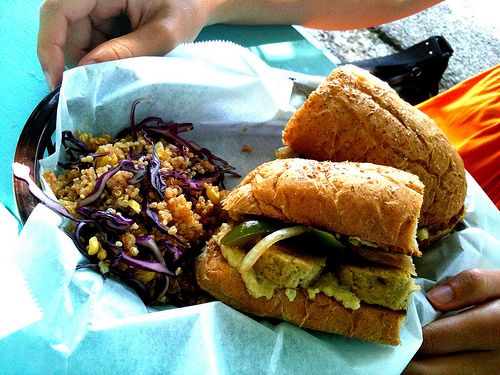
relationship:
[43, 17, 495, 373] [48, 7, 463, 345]
bench next to table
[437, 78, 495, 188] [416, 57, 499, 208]
wrinkles are on shirt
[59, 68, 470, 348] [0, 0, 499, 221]
food on top of table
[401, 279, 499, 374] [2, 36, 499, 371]
fingers on white paper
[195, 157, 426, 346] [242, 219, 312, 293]
sandwich with onion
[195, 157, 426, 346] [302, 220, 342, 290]
sandwich with pepper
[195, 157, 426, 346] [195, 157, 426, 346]
sandwich with sandwich